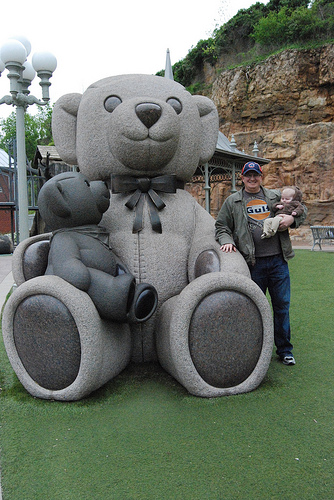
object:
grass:
[1, 247, 333, 499]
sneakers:
[282, 350, 300, 363]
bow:
[241, 194, 268, 209]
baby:
[261, 181, 306, 238]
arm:
[294, 202, 308, 228]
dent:
[28, 381, 90, 409]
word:
[242, 204, 270, 215]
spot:
[108, 263, 130, 278]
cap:
[238, 158, 266, 179]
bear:
[3, 72, 274, 403]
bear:
[37, 170, 162, 322]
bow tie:
[107, 164, 188, 238]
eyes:
[163, 93, 183, 116]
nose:
[136, 96, 162, 128]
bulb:
[30, 45, 59, 79]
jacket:
[212, 182, 309, 263]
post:
[7, 46, 52, 254]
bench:
[304, 217, 332, 256]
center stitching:
[128, 208, 152, 365]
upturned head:
[36, 165, 114, 233]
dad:
[214, 159, 307, 369]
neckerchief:
[45, 220, 119, 257]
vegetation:
[156, 2, 334, 88]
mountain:
[155, 26, 334, 251]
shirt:
[241, 188, 282, 265]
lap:
[0, 257, 274, 411]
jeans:
[250, 256, 292, 363]